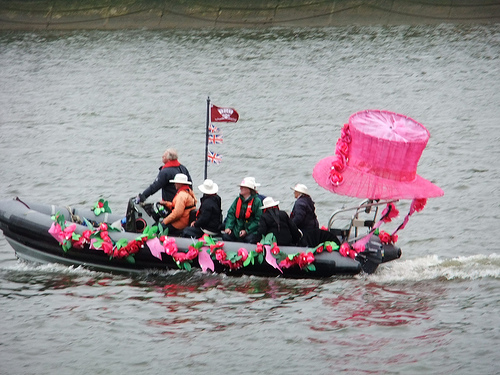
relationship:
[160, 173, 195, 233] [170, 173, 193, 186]
woman wearing hat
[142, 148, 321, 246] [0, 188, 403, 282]
people are sitting on boat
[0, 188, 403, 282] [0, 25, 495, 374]
boat in water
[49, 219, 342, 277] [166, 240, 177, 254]
decorations has flower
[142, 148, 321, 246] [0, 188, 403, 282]
people are on top of boat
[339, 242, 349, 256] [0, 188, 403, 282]
flower on side of boat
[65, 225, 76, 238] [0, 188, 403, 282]
flower on side of boat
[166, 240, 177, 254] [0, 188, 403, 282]
flower on side of boat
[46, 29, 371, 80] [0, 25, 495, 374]
ripples on top of water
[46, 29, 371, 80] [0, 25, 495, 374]
ripples on surface of water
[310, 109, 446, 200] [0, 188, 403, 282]
hat attached to boat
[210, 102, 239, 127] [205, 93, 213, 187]
flag tied to pole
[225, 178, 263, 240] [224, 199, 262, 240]
woman wearing coat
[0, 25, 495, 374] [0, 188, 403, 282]
water under boat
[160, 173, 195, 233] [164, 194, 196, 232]
woman wearing coat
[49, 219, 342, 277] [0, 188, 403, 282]
decorations on side of boat